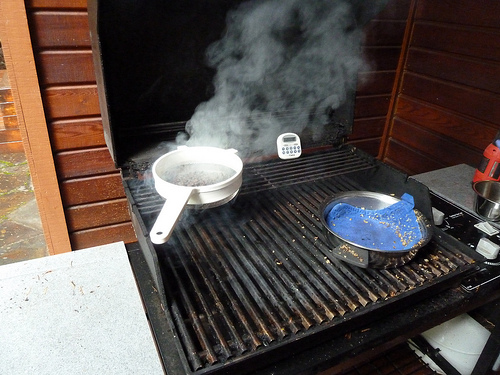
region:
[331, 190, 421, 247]
dirty blue pot holder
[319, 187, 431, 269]
stainless steel bowl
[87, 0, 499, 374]
black barbecue grill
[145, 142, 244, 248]
white plastic camping pan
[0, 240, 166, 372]
white plastic cutting board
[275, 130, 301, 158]
small white kitchen timer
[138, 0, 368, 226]
cloud of white smoke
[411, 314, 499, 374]
white plastic container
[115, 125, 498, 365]
This is a kitchen grill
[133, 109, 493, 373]
This is a kitchen grill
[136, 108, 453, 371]
This is a kitchen grill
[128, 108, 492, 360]
This is a kitchen grill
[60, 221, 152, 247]
This is a brick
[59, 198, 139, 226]
This is a brick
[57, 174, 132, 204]
This is a brick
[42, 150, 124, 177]
This is a brick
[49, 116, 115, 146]
This is a brick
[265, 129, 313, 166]
timer on back of grill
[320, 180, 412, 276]
steel pan on grill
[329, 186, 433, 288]
blue cloth in pan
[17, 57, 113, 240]
brown wall behind grill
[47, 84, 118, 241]
wooden slats on wall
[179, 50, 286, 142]
smoke rising from pan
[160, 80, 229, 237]
white pan on grill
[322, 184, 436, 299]
steel pan on grill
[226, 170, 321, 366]
black bars on grill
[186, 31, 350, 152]
steam rising from pan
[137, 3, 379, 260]
smoke over a grill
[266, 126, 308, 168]
a timer over a grill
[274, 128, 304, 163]
the timer is white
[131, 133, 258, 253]
a strainer over a grill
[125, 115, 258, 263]
a bowl on a grill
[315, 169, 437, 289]
a pot on a grill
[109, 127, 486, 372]
a square outdoor grill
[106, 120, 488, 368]
the grill is black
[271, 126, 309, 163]
a small white timer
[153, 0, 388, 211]
smoke in the air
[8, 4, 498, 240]
a brown wooden wall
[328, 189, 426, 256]
blue item on pot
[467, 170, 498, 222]
silver bowl on the side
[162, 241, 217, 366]
black metal rail on the grill